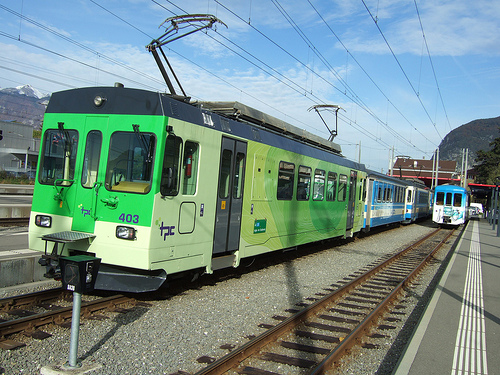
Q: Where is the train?
A: On the tracks.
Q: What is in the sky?
A: Clouds.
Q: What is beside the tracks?
A: Pedestrian area.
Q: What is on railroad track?
A: A train.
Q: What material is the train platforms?
A: Concrete.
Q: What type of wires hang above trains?
A: Electrical wires.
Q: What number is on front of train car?
A: Number is 403.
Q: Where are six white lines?
A: On train platform.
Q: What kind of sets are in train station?
A: Train tracks.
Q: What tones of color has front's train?
A: Dark and dim green.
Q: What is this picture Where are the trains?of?
A: On rail tracks at the platforms.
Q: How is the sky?
A: Blue sky has some white clouds.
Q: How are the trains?
A: Green and blue colored and with closed windows.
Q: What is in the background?
A: Sky and a hill.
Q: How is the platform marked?
A: The platform is marked with six white long parallel lines.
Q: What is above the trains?
A: Power cables and pantographs.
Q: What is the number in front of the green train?
A: 403.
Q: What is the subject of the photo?
A: Train.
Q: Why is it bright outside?
A: It's daytime.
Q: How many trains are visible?
A: Two.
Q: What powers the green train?
A: Electricity.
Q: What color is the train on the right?
A: Blue.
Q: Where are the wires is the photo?
A: Above the trains.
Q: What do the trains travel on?
A: Tracks.